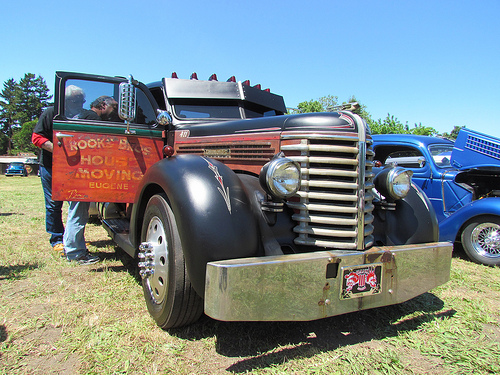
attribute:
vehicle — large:
[38, 61, 470, 340]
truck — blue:
[356, 106, 499, 296]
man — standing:
[35, 147, 62, 255]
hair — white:
[62, 82, 84, 98]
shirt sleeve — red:
[30, 132, 47, 145]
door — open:
[56, 70, 148, 199]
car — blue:
[5, 157, 28, 181]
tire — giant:
[146, 275, 182, 324]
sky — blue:
[299, 24, 363, 60]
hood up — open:
[451, 129, 499, 181]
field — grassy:
[8, 184, 45, 201]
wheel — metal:
[456, 214, 497, 267]